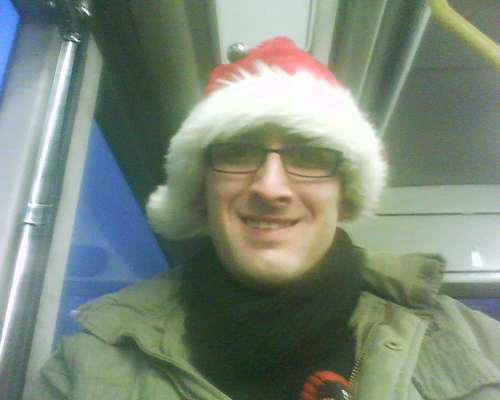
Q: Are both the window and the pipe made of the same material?
A: No, the window is made of glass and the pipe is made of metal.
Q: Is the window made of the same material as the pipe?
A: No, the window is made of glass and the pipe is made of metal.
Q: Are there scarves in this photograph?
A: Yes, there is a scarf.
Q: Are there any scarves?
A: Yes, there is a scarf.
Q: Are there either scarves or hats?
A: Yes, there is a scarf.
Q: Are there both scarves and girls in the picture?
A: No, there is a scarf but no girls.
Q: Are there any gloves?
A: No, there are no gloves.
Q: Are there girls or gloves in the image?
A: No, there are no gloves or girls.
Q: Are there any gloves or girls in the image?
A: No, there are no gloves or girls.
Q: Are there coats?
A: Yes, there is a coat.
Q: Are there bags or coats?
A: Yes, there is a coat.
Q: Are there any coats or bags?
A: Yes, there is a coat.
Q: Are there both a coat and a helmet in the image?
A: No, there is a coat but no helmets.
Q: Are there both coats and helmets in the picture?
A: No, there is a coat but no helmets.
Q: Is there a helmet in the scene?
A: No, there are no helmets.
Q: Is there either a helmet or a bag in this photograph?
A: No, there are no helmets or bags.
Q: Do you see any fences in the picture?
A: No, there are no fences.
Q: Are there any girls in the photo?
A: No, there are no girls.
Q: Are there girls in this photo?
A: No, there are no girls.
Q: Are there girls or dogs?
A: No, there are no girls or dogs.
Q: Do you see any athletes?
A: No, there are no athletes.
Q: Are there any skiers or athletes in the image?
A: No, there are no athletes or skiers.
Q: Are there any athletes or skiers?
A: No, there are no athletes or skiers.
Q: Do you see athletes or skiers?
A: No, there are no athletes or skiers.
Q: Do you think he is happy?
A: Yes, the man is happy.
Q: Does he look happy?
A: Yes, the man is happy.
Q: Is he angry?
A: No, the man is happy.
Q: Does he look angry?
A: No, the man is happy.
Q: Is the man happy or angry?
A: The man is happy.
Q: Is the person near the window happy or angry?
A: The man is happy.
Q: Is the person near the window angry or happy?
A: The man is happy.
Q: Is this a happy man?
A: Yes, this is a happy man.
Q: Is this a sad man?
A: No, this is a happy man.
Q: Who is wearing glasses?
A: The man is wearing glasses.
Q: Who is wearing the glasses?
A: The man is wearing glasses.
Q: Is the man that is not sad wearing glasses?
A: Yes, the man is wearing glasses.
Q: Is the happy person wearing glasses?
A: Yes, the man is wearing glasses.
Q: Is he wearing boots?
A: No, the man is wearing glasses.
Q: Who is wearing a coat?
A: The man is wearing a coat.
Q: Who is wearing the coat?
A: The man is wearing a coat.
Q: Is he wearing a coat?
A: Yes, the man is wearing a coat.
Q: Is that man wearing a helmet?
A: No, the man is wearing a coat.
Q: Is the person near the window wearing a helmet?
A: No, the man is wearing a coat.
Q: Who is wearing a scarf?
A: The man is wearing a scarf.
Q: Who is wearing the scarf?
A: The man is wearing a scarf.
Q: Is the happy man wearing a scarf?
A: Yes, the man is wearing a scarf.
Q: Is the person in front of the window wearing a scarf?
A: Yes, the man is wearing a scarf.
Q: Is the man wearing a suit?
A: No, the man is wearing a scarf.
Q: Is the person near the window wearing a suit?
A: No, the man is wearing a scarf.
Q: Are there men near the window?
A: Yes, there is a man near the window.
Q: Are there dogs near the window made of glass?
A: No, there is a man near the window.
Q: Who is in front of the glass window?
A: The man is in front of the window.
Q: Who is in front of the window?
A: The man is in front of the window.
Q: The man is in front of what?
A: The man is in front of the window.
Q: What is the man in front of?
A: The man is in front of the window.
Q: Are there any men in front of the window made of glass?
A: Yes, there is a man in front of the window.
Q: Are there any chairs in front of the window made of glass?
A: No, there is a man in front of the window.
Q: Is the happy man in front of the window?
A: Yes, the man is in front of the window.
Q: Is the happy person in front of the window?
A: Yes, the man is in front of the window.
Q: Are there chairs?
A: No, there are no chairs.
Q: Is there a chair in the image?
A: No, there are no chairs.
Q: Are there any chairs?
A: No, there are no chairs.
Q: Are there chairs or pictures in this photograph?
A: No, there are no chairs or pictures.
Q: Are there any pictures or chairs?
A: No, there are no chairs or pictures.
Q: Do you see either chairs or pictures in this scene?
A: No, there are no chairs or pictures.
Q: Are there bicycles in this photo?
A: No, there are no bicycles.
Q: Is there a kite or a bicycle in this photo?
A: No, there are no bicycles or kites.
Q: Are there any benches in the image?
A: No, there are no benches.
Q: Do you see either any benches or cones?
A: No, there are no benches or cones.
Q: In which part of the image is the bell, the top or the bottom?
A: The bell is in the top of the image.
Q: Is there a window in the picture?
A: Yes, there is a window.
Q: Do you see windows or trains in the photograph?
A: Yes, there is a window.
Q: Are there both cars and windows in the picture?
A: No, there is a window but no cars.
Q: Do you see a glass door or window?
A: Yes, there is a glass window.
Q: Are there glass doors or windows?
A: Yes, there is a glass window.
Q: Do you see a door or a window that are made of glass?
A: Yes, the window is made of glass.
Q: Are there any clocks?
A: No, there are no clocks.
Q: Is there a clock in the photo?
A: No, there are no clocks.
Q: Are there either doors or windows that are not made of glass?
A: No, there is a window but it is made of glass.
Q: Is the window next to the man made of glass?
A: Yes, the window is made of glass.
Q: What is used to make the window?
A: The window is made of glass.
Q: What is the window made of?
A: The window is made of glass.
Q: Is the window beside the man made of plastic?
A: No, the window is made of glass.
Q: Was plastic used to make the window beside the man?
A: No, the window is made of glass.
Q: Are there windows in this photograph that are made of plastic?
A: No, there is a window but it is made of glass.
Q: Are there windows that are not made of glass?
A: No, there is a window but it is made of glass.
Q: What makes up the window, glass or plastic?
A: The window is made of glass.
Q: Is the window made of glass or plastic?
A: The window is made of glass.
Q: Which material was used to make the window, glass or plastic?
A: The window is made of glass.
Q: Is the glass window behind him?
A: Yes, the window is behind the man.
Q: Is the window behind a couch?
A: No, the window is behind the man.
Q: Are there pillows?
A: No, there are no pillows.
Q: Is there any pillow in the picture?
A: No, there are no pillows.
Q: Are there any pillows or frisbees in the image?
A: No, there are no pillows or frisbees.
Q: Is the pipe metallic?
A: Yes, the pipe is metallic.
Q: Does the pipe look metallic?
A: Yes, the pipe is metallic.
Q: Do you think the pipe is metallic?
A: Yes, the pipe is metallic.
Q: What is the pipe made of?
A: The pipe is made of metal.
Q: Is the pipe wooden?
A: No, the pipe is metallic.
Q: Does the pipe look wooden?
A: No, the pipe is metallic.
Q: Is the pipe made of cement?
A: No, the pipe is made of metal.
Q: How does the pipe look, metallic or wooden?
A: The pipe is metallic.